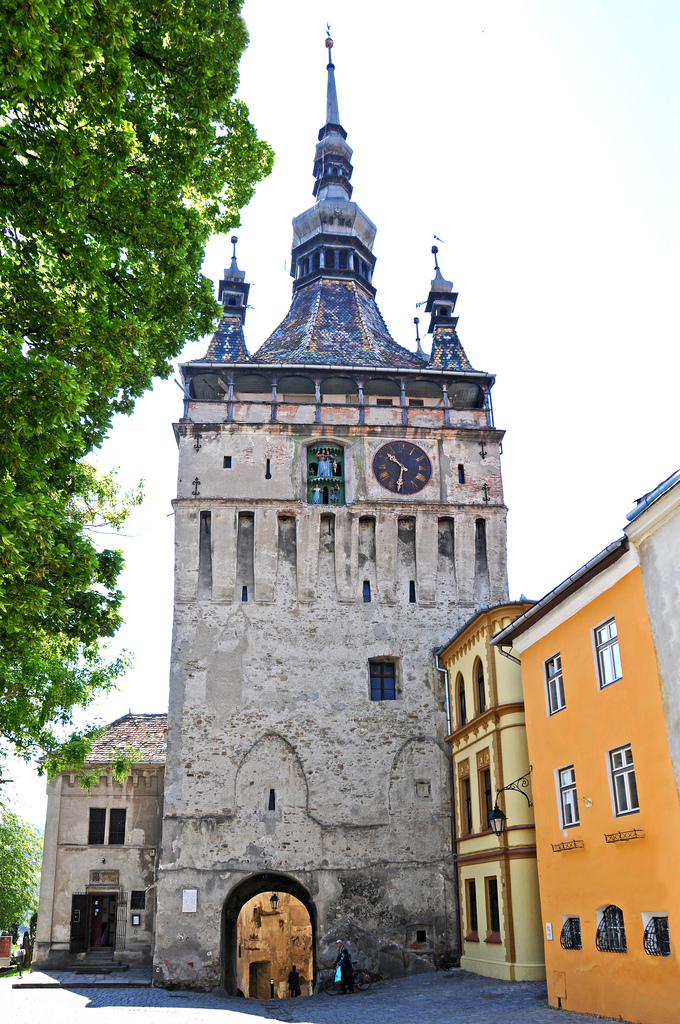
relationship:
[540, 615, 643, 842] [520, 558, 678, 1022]
windows on yellow building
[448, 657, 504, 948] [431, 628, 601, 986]
windows on building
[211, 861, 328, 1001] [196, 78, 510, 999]
archway though tower